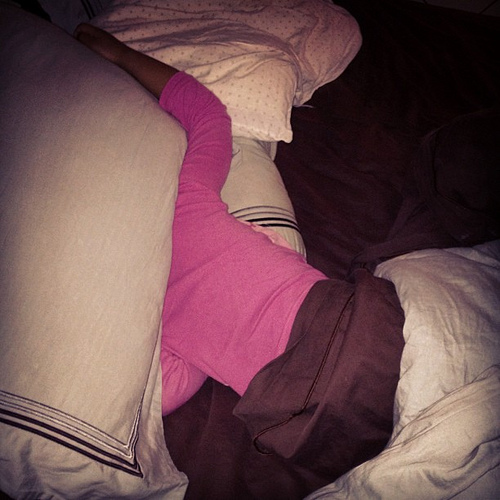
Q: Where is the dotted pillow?
A: On a bed.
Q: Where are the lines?
A: On the side of a pillow.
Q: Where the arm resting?
A: On a pillow.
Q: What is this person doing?
A: Laying in bed.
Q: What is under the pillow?
A: Person's head.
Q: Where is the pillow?
A: Over the person's head.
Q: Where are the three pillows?
A: On the bed.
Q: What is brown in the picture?
A: The sheets.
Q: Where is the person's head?
A: Under the pillow.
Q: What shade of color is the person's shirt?
A: Pink.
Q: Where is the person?
A: Bed.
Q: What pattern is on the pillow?
A: Lines.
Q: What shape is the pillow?
A: Square.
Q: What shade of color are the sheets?
A: Maroon and tan.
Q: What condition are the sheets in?
A: Wrinkled.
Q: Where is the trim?
A: On pillow.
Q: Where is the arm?
A: Above pillow.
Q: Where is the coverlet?
A: On bed.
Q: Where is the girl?
A: In bed.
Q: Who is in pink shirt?
A: A girl.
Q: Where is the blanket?
A: On girl.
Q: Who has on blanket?
A: A girl.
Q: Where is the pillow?
A: On bed.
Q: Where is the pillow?
A: On the person's head.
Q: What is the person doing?
A: Sleeping.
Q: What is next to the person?
A: Pillows.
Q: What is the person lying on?
A: A bed.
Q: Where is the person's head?
A: Under the pillow.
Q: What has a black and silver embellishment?
A: The pillow.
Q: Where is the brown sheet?
A: On the bed.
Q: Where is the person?
A: Sleeping under the pillow.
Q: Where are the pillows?
A: On the bed.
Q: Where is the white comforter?
A: On the bed.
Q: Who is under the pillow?
A: A person.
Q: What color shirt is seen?
A: Pick.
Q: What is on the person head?
A: Pillow.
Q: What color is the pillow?
A: White.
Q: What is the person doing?
A: Sleeping.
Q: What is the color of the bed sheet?
A: Maroon.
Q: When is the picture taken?
A: Nighttime.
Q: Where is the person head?
A: Under the pillow.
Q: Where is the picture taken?
A: In a bedroom.